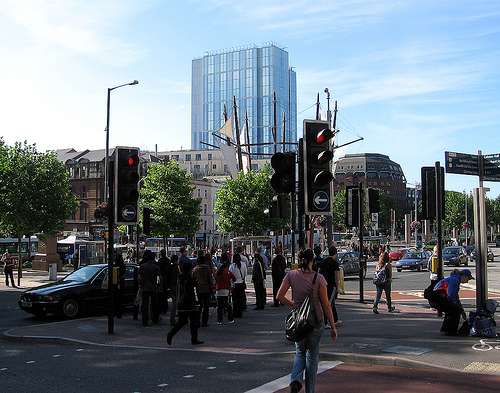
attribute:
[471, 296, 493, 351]
item — picked up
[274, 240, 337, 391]
woman — black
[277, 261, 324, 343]
bag — large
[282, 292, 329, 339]
bag — black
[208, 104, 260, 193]
arrow — blue, white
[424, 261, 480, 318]
lady — wearing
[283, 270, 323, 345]
bag — black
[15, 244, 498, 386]
street — white, dotted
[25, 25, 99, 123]
clouds — high elevation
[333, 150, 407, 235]
building — interesting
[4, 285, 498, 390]
sidewalk — busy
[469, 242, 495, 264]
car — waiting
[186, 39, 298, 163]
building — tallest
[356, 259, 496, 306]
pavement — red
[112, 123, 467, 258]
lights — red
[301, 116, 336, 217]
light — red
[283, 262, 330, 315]
shirt — brown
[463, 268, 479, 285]
cap — blue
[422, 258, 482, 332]
lady — kneeling down